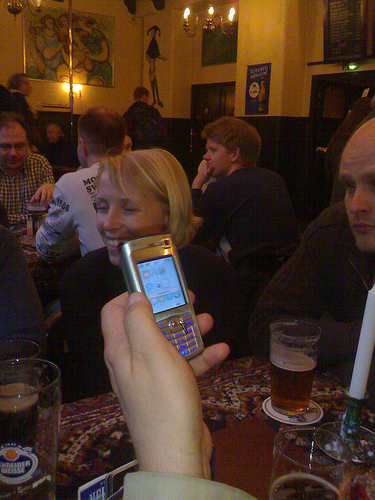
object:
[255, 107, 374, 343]
people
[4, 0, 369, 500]
restaurant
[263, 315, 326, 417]
glass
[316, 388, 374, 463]
holder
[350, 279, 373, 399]
candle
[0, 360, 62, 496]
pint glass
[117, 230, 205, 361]
cell phone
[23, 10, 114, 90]
picture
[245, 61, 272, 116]
advertisement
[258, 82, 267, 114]
beer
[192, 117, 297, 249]
man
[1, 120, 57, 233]
man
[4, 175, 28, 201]
plaid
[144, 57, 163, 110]
poster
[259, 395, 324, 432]
coaster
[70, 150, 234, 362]
woman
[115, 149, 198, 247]
woman's hair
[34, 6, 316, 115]
wall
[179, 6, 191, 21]
lights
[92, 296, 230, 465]
hand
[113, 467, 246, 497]
sleeve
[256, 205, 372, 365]
jacket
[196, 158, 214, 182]
hand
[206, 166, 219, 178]
chin